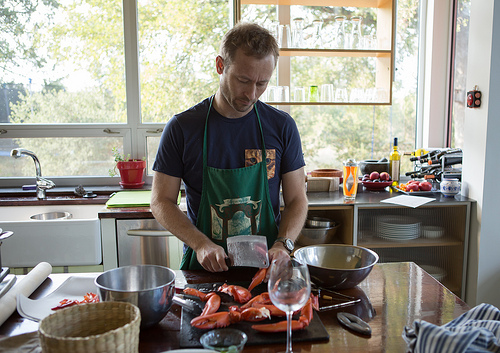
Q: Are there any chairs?
A: No, there are no chairs.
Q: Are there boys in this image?
A: No, there are no boys.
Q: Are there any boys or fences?
A: No, there are no boys or fences.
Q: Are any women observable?
A: No, there are no women.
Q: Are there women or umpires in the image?
A: No, there are no women or umpires.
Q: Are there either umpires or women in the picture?
A: No, there are no women or umpires.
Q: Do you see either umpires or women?
A: No, there are no women or umpires.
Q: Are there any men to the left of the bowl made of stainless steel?
A: Yes, there is a man to the left of the bowl.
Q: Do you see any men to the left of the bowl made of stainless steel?
A: Yes, there is a man to the left of the bowl.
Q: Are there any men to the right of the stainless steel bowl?
A: No, the man is to the left of the bowl.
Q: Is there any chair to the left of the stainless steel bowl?
A: No, there is a man to the left of the bowl.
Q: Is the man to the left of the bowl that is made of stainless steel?
A: Yes, the man is to the left of the bowl.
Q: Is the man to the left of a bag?
A: No, the man is to the left of the bowl.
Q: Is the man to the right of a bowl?
A: No, the man is to the left of a bowl.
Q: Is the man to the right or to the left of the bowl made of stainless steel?
A: The man is to the left of the bowl.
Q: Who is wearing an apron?
A: The man is wearing an apron.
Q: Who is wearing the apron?
A: The man is wearing an apron.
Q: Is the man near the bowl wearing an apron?
A: Yes, the man is wearing an apron.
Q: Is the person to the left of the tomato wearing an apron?
A: Yes, the man is wearing an apron.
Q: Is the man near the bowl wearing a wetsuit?
A: No, the man is wearing an apron.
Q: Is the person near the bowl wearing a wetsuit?
A: No, the man is wearing an apron.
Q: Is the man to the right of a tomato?
A: No, the man is to the left of a tomato.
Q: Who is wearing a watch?
A: The man is wearing a watch.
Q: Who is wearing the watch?
A: The man is wearing a watch.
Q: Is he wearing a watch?
A: Yes, the man is wearing a watch.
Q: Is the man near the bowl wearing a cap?
A: No, the man is wearing a watch.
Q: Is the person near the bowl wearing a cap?
A: No, the man is wearing a watch.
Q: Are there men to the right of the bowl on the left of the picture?
A: Yes, there is a man to the right of the bowl.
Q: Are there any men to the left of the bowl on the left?
A: No, the man is to the right of the bowl.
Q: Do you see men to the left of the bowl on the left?
A: No, the man is to the right of the bowl.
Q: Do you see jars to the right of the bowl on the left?
A: No, there is a man to the right of the bowl.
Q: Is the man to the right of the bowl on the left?
A: Yes, the man is to the right of the bowl.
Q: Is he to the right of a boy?
A: No, the man is to the right of the bowl.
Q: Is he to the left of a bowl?
A: No, the man is to the right of a bowl.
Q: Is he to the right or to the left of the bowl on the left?
A: The man is to the right of the bowl.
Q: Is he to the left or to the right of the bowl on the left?
A: The man is to the right of the bowl.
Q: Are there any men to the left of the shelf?
A: Yes, there is a man to the left of the shelf.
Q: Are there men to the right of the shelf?
A: No, the man is to the left of the shelf.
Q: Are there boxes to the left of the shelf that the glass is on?
A: No, there is a man to the left of the shelf.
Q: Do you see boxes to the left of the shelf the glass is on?
A: No, there is a man to the left of the shelf.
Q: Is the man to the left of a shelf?
A: Yes, the man is to the left of a shelf.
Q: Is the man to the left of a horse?
A: No, the man is to the left of a shelf.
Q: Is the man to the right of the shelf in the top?
A: No, the man is to the left of the shelf.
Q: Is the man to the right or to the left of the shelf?
A: The man is to the left of the shelf.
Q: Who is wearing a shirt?
A: The man is wearing a shirt.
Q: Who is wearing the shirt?
A: The man is wearing a shirt.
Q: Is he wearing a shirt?
A: Yes, the man is wearing a shirt.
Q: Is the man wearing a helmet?
A: No, the man is wearing a shirt.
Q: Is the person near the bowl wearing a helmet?
A: No, the man is wearing a shirt.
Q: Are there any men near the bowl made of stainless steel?
A: Yes, there is a man near the bowl.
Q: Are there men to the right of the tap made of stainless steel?
A: Yes, there is a man to the right of the faucet.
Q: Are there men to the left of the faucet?
A: No, the man is to the right of the faucet.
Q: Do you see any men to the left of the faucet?
A: No, the man is to the right of the faucet.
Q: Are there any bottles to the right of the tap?
A: No, there is a man to the right of the tap.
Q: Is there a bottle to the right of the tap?
A: No, there is a man to the right of the tap.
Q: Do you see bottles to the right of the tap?
A: No, there is a man to the right of the tap.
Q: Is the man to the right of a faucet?
A: Yes, the man is to the right of a faucet.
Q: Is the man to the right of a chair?
A: No, the man is to the right of a faucet.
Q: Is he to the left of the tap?
A: No, the man is to the right of the tap.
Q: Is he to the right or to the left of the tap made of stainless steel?
A: The man is to the right of the tap.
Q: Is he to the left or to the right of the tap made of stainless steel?
A: The man is to the right of the tap.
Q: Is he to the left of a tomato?
A: Yes, the man is to the left of a tomato.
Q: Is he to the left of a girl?
A: No, the man is to the left of a tomato.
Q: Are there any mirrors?
A: No, there are no mirrors.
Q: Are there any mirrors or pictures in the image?
A: No, there are no mirrors or pictures.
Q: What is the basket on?
A: The basket is on the counter.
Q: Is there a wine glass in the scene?
A: Yes, there is a wine glass.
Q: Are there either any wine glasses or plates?
A: Yes, there is a wine glass.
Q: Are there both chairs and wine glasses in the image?
A: No, there is a wine glass but no chairs.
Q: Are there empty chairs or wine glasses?
A: Yes, there is an empty wine glass.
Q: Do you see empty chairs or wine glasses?
A: Yes, there is an empty wine glass.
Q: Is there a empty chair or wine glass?
A: Yes, there is an empty wine glass.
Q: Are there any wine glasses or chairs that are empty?
A: Yes, the wine glass is empty.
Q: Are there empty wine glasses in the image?
A: Yes, there is an empty wine glass.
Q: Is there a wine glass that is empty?
A: Yes, there is a wine glass that is empty.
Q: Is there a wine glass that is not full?
A: Yes, there is a empty wine glass.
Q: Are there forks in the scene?
A: No, there are no forks.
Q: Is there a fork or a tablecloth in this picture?
A: No, there are no forks or tablecloths.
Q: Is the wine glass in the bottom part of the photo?
A: Yes, the wine glass is in the bottom of the image.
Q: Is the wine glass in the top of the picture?
A: No, the wine glass is in the bottom of the image.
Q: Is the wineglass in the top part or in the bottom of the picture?
A: The wineglass is in the bottom of the image.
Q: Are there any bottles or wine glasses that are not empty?
A: No, there is a wine glass but it is empty.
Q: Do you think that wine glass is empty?
A: Yes, the wine glass is empty.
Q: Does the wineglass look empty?
A: Yes, the wineglass is empty.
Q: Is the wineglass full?
A: No, the wineglass is empty.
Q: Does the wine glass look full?
A: No, the wine glass is empty.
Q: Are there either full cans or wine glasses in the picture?
A: No, there is a wine glass but it is empty.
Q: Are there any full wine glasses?
A: No, there is a wine glass but it is empty.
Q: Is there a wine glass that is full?
A: No, there is a wine glass but it is empty.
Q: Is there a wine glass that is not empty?
A: No, there is a wine glass but it is empty.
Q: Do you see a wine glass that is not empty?
A: No, there is a wine glass but it is empty.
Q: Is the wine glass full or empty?
A: The wine glass is empty.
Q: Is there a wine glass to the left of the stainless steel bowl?
A: Yes, there is a wine glass to the left of the bowl.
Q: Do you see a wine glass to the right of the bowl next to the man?
A: No, the wine glass is to the left of the bowl.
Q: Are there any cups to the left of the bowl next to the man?
A: No, there is a wine glass to the left of the bowl.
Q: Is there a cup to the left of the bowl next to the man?
A: No, there is a wine glass to the left of the bowl.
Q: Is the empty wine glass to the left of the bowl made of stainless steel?
A: Yes, the wine glass is to the left of the bowl.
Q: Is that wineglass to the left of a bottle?
A: No, the wineglass is to the left of the bowl.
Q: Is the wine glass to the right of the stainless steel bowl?
A: No, the wine glass is to the left of the bowl.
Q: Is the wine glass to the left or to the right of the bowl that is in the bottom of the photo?
A: The wine glass is to the left of the bowl.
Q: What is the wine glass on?
A: The wine glass is on the counter.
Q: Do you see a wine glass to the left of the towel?
A: Yes, there is a wine glass to the left of the towel.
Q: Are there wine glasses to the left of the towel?
A: Yes, there is a wine glass to the left of the towel.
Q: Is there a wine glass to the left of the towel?
A: Yes, there is a wine glass to the left of the towel.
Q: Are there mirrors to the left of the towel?
A: No, there is a wine glass to the left of the towel.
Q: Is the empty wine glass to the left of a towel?
A: Yes, the wineglass is to the left of a towel.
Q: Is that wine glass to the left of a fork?
A: No, the wine glass is to the left of a towel.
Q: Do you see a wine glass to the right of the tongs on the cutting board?
A: Yes, there is a wine glass to the right of the tongs.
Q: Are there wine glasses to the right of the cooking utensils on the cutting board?
A: Yes, there is a wine glass to the right of the tongs.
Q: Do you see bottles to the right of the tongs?
A: No, there is a wine glass to the right of the tongs.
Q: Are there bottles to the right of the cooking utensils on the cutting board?
A: No, there is a wine glass to the right of the tongs.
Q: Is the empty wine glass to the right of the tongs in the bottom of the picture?
A: Yes, the wine glass is to the right of the tongs.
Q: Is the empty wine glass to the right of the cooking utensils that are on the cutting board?
A: Yes, the wine glass is to the right of the tongs.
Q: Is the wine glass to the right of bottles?
A: No, the wine glass is to the right of the tongs.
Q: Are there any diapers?
A: No, there are no diapers.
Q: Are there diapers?
A: No, there are no diapers.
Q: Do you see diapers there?
A: No, there are no diapers.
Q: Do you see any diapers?
A: No, there are no diapers.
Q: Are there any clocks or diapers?
A: No, there are no diapers or clocks.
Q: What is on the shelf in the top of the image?
A: The glass is on the shelf.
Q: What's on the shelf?
A: The glass is on the shelf.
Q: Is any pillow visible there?
A: No, there are no pillows.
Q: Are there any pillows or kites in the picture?
A: No, there are no pillows or kites.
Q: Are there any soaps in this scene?
A: No, there are no soaps.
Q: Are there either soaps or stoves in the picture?
A: No, there are no soaps or stoves.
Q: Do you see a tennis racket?
A: No, there are no rackets.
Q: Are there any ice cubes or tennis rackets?
A: No, there are no tennis rackets or ice cubes.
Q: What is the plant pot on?
A: The plant pot is on the counter.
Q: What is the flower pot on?
A: The plant pot is on the counter.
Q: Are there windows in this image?
A: Yes, there is a window.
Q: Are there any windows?
A: Yes, there is a window.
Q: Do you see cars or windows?
A: Yes, there is a window.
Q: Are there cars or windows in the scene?
A: Yes, there is a window.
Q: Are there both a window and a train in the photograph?
A: No, there is a window but no trains.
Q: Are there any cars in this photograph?
A: No, there are no cars.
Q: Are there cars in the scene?
A: No, there are no cars.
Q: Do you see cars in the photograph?
A: No, there are no cars.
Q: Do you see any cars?
A: No, there are no cars.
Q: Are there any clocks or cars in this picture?
A: No, there are no cars or clocks.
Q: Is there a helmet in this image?
A: No, there are no helmets.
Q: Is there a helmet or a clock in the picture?
A: No, there are no helmets or clocks.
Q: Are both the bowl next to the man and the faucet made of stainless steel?
A: Yes, both the bowl and the faucet are made of stainless steel.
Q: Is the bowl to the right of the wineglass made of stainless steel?
A: Yes, the bowl is made of stainless steel.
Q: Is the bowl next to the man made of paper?
A: No, the bowl is made of stainless steel.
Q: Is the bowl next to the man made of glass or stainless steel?
A: The bowl is made of stainless steel.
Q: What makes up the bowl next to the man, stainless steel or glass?
A: The bowl is made of stainless steel.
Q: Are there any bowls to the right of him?
A: Yes, there is a bowl to the right of the man.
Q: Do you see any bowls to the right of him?
A: Yes, there is a bowl to the right of the man.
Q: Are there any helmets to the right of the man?
A: No, there is a bowl to the right of the man.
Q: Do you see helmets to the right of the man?
A: No, there is a bowl to the right of the man.